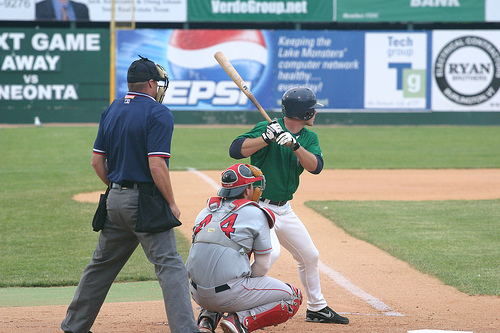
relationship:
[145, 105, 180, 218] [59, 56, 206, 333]
arm of a guard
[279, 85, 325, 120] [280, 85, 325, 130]
helmet on head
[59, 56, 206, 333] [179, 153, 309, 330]
guard standing behind catcher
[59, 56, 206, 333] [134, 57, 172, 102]
guard wearing face mask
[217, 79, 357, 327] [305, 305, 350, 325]
batter wearing cleat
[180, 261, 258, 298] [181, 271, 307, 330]
belt on pants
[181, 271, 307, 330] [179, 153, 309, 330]
pants on catcher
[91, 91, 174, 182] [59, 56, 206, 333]
shirt on guard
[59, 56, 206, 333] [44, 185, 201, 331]
guard wearing pants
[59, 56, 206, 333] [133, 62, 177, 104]
guard wearing guard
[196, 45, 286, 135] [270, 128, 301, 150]
bat in hand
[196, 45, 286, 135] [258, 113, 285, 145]
bat in hand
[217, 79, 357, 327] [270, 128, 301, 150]
batter has hand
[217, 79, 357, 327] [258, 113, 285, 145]
batter has hand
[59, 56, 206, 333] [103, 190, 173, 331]
guard wearing pants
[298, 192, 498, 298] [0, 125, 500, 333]
grass on baseball field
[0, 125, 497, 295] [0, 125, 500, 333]
grass on baseball field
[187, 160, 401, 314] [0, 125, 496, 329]
white line on baseball field